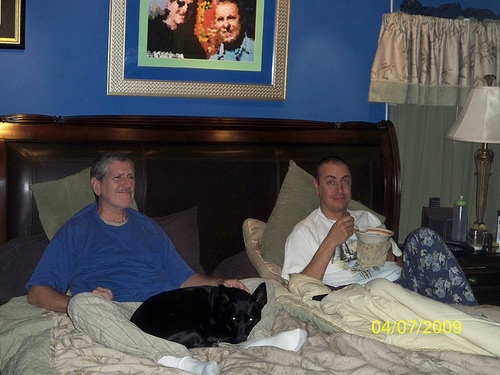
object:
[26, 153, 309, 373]
man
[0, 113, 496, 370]
bed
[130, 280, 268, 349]
dog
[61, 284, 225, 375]
legs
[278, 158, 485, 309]
man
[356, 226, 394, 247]
bowl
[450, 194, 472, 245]
bottle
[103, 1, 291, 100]
picture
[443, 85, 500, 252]
lamp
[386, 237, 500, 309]
night table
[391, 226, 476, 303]
pajama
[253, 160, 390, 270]
cushion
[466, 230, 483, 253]
glass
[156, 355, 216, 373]
sock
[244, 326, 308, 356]
sock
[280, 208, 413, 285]
shirt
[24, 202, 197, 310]
shirt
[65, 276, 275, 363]
pants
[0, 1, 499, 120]
wall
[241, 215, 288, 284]
pillow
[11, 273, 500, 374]
comforter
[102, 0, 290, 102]
frame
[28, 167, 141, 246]
pillow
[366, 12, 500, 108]
curtain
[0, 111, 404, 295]
headboard